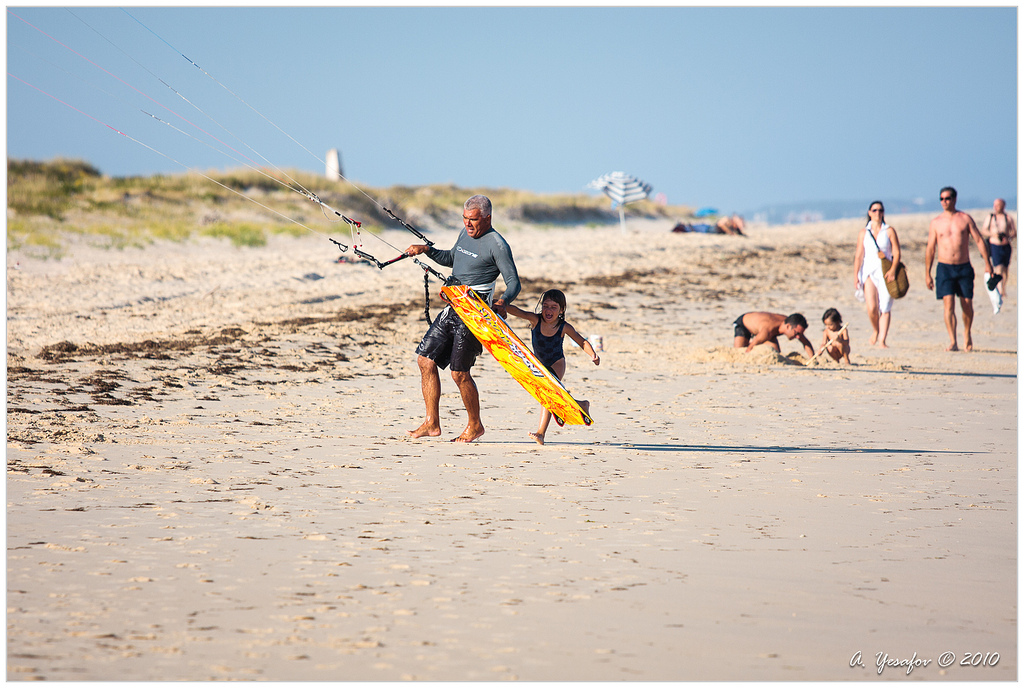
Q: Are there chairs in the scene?
A: No, there are no chairs.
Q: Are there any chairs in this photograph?
A: No, there are no chairs.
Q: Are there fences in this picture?
A: No, there are no fences.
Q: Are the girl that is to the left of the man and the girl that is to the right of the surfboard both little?
A: Yes, both the girl and the girl are little.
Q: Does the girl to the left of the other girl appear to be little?
A: Yes, the girl is little.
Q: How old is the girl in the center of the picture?
A: The girl is little.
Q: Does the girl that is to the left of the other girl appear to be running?
A: Yes, the girl is running.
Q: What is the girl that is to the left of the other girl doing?
A: The girl is running.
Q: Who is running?
A: The girl is running.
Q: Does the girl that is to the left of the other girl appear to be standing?
A: No, the girl is running.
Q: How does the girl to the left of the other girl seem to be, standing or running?
A: The girl is running.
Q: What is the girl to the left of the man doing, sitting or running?
A: The girl is running.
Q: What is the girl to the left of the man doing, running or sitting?
A: The girl is running.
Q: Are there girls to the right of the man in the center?
A: Yes, there is a girl to the right of the man.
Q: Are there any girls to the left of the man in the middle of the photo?
A: No, the girl is to the right of the man.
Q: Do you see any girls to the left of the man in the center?
A: No, the girl is to the right of the man.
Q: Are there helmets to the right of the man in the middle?
A: No, there is a girl to the right of the man.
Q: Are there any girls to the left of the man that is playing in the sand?
A: Yes, there is a girl to the left of the man.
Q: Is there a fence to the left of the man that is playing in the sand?
A: No, there is a girl to the left of the man.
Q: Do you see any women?
A: Yes, there is a woman.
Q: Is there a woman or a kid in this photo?
A: Yes, there is a woman.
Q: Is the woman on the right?
A: Yes, the woman is on the right of the image.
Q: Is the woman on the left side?
A: No, the woman is on the right of the image.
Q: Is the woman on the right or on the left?
A: The woman is on the right of the image.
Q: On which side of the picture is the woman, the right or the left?
A: The woman is on the right of the image.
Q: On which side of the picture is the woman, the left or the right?
A: The woman is on the right of the image.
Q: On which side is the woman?
A: The woman is on the right of the image.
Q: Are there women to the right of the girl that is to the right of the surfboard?
A: Yes, there is a woman to the right of the girl.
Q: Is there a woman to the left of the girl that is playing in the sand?
A: No, the woman is to the right of the girl.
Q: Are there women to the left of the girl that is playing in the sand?
A: No, the woman is to the right of the girl.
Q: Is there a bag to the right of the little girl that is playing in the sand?
A: No, there is a woman to the right of the girl.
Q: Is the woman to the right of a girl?
A: Yes, the woman is to the right of a girl.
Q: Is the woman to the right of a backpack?
A: No, the woman is to the right of a girl.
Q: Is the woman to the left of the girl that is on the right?
A: No, the woman is to the right of the girl.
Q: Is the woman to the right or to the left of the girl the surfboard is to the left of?
A: The woman is to the right of the girl.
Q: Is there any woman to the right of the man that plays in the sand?
A: Yes, there is a woman to the right of the man.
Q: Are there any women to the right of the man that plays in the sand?
A: Yes, there is a woman to the right of the man.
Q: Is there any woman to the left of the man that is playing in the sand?
A: No, the woman is to the right of the man.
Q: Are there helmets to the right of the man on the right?
A: No, there is a woman to the right of the man.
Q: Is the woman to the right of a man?
A: Yes, the woman is to the right of a man.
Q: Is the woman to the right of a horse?
A: No, the woman is to the right of a man.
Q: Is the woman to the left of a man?
A: No, the woman is to the right of a man.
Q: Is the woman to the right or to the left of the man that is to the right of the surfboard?
A: The woman is to the right of the man.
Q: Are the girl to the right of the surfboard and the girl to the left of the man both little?
A: Yes, both the girl and the girl are little.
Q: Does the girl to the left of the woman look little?
A: Yes, the girl is little.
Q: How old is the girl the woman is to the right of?
A: The girl is little.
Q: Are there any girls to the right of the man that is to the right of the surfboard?
A: Yes, there is a girl to the right of the man.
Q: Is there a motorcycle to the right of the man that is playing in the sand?
A: No, there is a girl to the right of the man.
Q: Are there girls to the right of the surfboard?
A: Yes, there is a girl to the right of the surfboard.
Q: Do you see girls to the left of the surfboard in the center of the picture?
A: No, the girl is to the right of the surfboard.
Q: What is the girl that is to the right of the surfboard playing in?
A: The girl is playing in the sand.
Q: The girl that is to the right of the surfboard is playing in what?
A: The girl is playing in the sand.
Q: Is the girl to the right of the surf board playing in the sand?
A: Yes, the girl is playing in the sand.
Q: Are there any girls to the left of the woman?
A: Yes, there is a girl to the left of the woman.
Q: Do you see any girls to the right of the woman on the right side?
A: No, the girl is to the left of the woman.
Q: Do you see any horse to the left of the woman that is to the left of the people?
A: No, there is a girl to the left of the woman.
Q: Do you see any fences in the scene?
A: No, there are no fences.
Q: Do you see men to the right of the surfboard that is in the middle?
A: Yes, there is a man to the right of the surfboard.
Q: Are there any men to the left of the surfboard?
A: No, the man is to the right of the surfboard.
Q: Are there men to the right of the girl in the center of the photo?
A: Yes, there is a man to the right of the girl.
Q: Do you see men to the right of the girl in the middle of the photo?
A: Yes, there is a man to the right of the girl.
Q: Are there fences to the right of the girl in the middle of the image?
A: No, there is a man to the right of the girl.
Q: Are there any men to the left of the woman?
A: Yes, there is a man to the left of the woman.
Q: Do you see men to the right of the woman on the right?
A: No, the man is to the left of the woman.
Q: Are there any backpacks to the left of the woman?
A: No, there is a man to the left of the woman.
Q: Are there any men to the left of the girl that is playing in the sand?
A: Yes, there is a man to the left of the girl.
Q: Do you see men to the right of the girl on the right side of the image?
A: No, the man is to the left of the girl.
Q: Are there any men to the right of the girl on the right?
A: No, the man is to the left of the girl.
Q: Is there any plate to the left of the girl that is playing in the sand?
A: No, there is a man to the left of the girl.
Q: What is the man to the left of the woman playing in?
A: The man is playing in the sand.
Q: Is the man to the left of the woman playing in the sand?
A: Yes, the man is playing in the sand.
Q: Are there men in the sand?
A: Yes, there is a man in the sand.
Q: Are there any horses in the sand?
A: No, there is a man in the sand.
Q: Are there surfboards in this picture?
A: Yes, there is a surfboard.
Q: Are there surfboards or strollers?
A: Yes, there is a surfboard.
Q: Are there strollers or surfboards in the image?
A: Yes, there is a surfboard.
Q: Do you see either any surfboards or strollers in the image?
A: Yes, there is a surfboard.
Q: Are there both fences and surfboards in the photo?
A: No, there is a surfboard but no fences.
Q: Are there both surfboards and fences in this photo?
A: No, there is a surfboard but no fences.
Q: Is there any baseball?
A: No, there are no baseballs.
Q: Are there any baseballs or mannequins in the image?
A: No, there are no baseballs or mannequins.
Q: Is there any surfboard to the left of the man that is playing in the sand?
A: Yes, there is a surfboard to the left of the man.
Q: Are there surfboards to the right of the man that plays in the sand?
A: No, the surfboard is to the left of the man.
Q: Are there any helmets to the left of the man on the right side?
A: No, there is a surfboard to the left of the man.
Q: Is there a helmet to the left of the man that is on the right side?
A: No, there is a surfboard to the left of the man.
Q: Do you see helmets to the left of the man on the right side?
A: No, there is a surfboard to the left of the man.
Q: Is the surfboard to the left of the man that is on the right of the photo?
A: Yes, the surfboard is to the left of the man.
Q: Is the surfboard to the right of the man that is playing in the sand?
A: No, the surfboard is to the left of the man.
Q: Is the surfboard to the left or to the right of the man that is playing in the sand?
A: The surfboard is to the left of the man.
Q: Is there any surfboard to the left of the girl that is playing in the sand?
A: Yes, there is a surfboard to the left of the girl.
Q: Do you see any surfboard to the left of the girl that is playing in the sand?
A: Yes, there is a surfboard to the left of the girl.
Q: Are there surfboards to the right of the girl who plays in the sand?
A: No, the surfboard is to the left of the girl.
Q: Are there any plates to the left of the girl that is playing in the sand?
A: No, there is a surfboard to the left of the girl.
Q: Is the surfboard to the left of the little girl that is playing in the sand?
A: Yes, the surfboard is to the left of the girl.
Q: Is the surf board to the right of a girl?
A: No, the surf board is to the left of a girl.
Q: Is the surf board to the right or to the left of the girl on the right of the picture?
A: The surf board is to the left of the girl.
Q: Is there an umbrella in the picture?
A: Yes, there is an umbrella.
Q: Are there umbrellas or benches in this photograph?
A: Yes, there is an umbrella.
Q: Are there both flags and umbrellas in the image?
A: No, there is an umbrella but no flags.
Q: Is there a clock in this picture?
A: No, there are no clocks.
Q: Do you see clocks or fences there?
A: No, there are no clocks or fences.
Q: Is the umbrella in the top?
A: Yes, the umbrella is in the top of the image.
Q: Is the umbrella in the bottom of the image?
A: No, the umbrella is in the top of the image.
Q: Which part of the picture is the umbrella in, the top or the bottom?
A: The umbrella is in the top of the image.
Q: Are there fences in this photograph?
A: No, there are no fences.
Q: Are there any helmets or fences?
A: No, there are no fences or helmets.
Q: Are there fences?
A: No, there are no fences.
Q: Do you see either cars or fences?
A: No, there are no fences or cars.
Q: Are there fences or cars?
A: No, there are no fences or cars.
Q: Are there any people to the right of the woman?
A: Yes, there are people to the right of the woman.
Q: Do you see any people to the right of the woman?
A: Yes, there are people to the right of the woman.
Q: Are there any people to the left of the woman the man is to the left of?
A: No, the people are to the right of the woman.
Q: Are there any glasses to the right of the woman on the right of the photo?
A: No, there are people to the right of the woman.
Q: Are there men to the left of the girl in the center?
A: Yes, there is a man to the left of the girl.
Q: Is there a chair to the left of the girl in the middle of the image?
A: No, there is a man to the left of the girl.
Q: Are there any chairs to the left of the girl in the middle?
A: No, there is a man to the left of the girl.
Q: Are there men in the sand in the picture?
A: Yes, there is a man in the sand.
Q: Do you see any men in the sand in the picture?
A: Yes, there is a man in the sand.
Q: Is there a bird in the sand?
A: No, there is a man in the sand.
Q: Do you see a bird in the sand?
A: No, there is a man in the sand.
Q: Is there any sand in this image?
A: Yes, there is sand.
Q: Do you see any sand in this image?
A: Yes, there is sand.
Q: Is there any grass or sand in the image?
A: Yes, there is sand.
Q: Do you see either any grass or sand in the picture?
A: Yes, there is sand.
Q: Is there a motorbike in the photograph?
A: No, there are no motorcycles.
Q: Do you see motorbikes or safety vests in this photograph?
A: No, there are no motorbikes or safety vests.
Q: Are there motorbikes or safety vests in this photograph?
A: No, there are no motorbikes or safety vests.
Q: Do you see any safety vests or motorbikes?
A: No, there are no motorbikes or safety vests.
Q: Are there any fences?
A: No, there are no fences.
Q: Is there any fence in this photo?
A: No, there are no fences.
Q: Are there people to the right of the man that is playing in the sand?
A: Yes, there are people to the right of the man.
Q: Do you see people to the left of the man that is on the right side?
A: No, the people are to the right of the man.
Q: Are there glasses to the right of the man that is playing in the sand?
A: No, there are people to the right of the man.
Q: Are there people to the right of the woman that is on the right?
A: Yes, there are people to the right of the woman.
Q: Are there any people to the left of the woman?
A: No, the people are to the right of the woman.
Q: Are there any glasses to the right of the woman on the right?
A: No, there are people to the right of the woman.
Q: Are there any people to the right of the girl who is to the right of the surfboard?
A: Yes, there are people to the right of the girl.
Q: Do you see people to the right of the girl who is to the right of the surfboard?
A: Yes, there are people to the right of the girl.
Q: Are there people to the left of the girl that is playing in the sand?
A: No, the people are to the right of the girl.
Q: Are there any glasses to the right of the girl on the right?
A: No, there are people to the right of the girl.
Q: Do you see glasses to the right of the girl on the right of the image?
A: No, there are people to the right of the girl.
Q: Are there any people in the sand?
A: Yes, there are people in the sand.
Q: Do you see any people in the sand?
A: Yes, there are people in the sand.